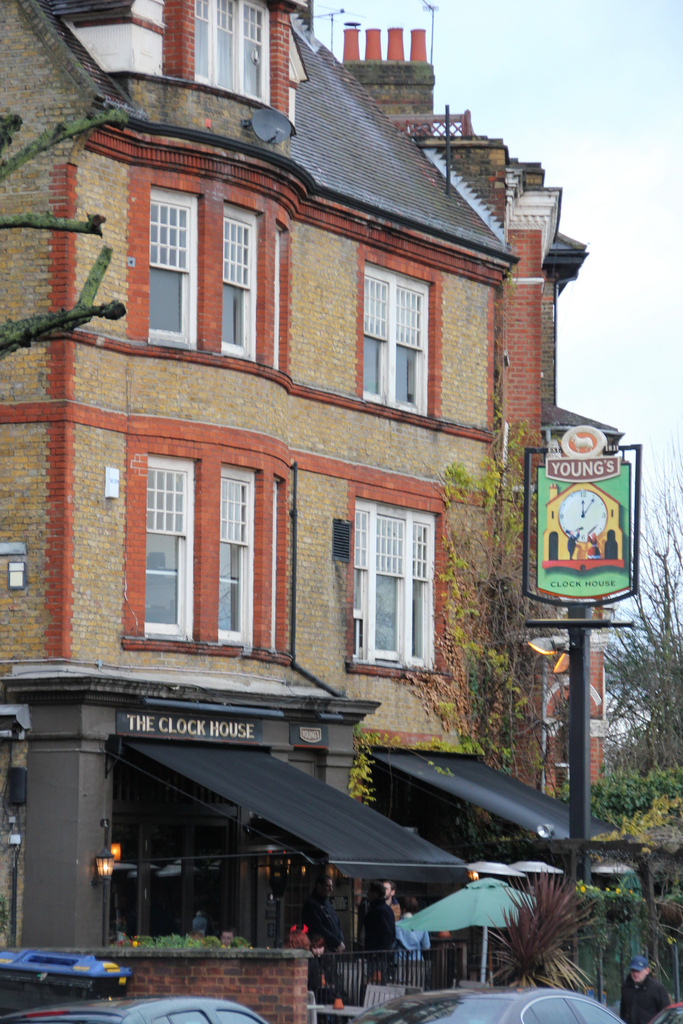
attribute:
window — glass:
[217, 464, 259, 642]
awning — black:
[365, 735, 619, 855]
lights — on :
[80, 829, 134, 881]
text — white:
[124, 713, 255, 742]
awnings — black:
[125, 722, 626, 903]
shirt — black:
[617, 982, 666, 1021]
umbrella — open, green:
[398, 878, 537, 937]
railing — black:
[304, 943, 522, 1005]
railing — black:
[309, 925, 649, 1021]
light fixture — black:
[85, 833, 132, 952]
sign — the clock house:
[110, 704, 266, 746]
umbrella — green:
[390, 876, 539, 985]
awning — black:
[109, 734, 472, 883]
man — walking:
[619, 950, 674, 1022]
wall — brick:
[6, 944, 315, 1022]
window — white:
[356, 495, 435, 668]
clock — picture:
[553, 487, 616, 546]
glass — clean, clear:
[146, 465, 182, 626]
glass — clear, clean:
[150, 532, 179, 568]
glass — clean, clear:
[148, 574, 176, 619]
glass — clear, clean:
[220, 476, 246, 539]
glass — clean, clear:
[373, 512, 405, 572]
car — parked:
[1, 995, 275, 1022]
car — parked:
[342, 984, 633, 1022]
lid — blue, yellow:
[6, 947, 132, 989]